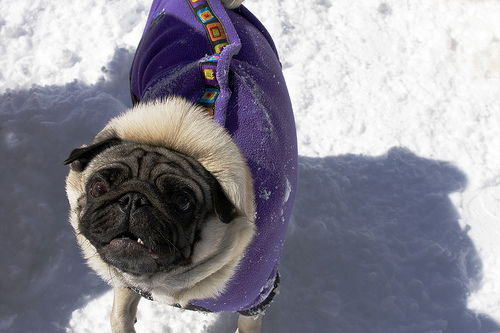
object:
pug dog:
[62, 0, 298, 333]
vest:
[129, 0, 300, 317]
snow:
[0, 0, 500, 331]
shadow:
[200, 144, 499, 331]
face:
[77, 143, 214, 276]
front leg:
[235, 308, 264, 332]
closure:
[197, 0, 242, 127]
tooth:
[137, 237, 141, 243]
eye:
[175, 194, 188, 210]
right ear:
[62, 138, 123, 172]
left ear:
[208, 173, 245, 225]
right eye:
[95, 181, 108, 194]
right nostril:
[118, 194, 131, 212]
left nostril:
[134, 194, 150, 215]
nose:
[117, 192, 150, 214]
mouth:
[100, 230, 159, 259]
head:
[78, 142, 217, 278]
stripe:
[184, 0, 229, 122]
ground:
[0, 0, 500, 332]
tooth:
[140, 239, 145, 245]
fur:
[64, 95, 256, 310]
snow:
[281, 175, 292, 206]